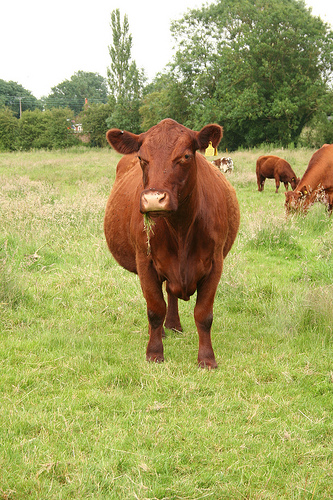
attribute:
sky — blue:
[0, 0, 174, 84]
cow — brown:
[252, 154, 299, 195]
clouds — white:
[2, 0, 203, 59]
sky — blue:
[2, 0, 331, 85]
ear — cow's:
[191, 118, 222, 152]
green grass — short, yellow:
[0, 152, 331, 499]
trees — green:
[3, 1, 332, 151]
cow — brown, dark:
[102, 115, 247, 374]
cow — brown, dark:
[250, 147, 308, 198]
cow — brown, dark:
[282, 142, 331, 228]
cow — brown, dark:
[204, 151, 240, 180]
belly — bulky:
[107, 181, 244, 267]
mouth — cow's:
[140, 206, 174, 215]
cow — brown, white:
[211, 156, 234, 174]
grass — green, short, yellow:
[0, 141, 329, 497]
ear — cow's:
[189, 123, 230, 155]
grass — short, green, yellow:
[0, 365, 331, 496]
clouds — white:
[6, 10, 91, 63]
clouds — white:
[7, 14, 89, 60]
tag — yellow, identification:
[204, 145, 216, 160]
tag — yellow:
[203, 143, 222, 162]